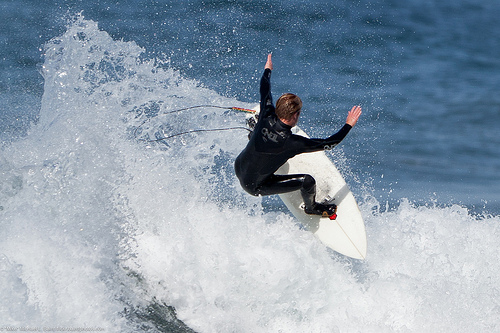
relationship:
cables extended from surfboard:
[149, 101, 257, 118] [241, 100, 368, 262]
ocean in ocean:
[2, 5, 498, 327] [2, 5, 498, 327]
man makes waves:
[231, 48, 361, 219] [90, 183, 305, 330]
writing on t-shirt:
[259, 126, 281, 146] [232, 114, 356, 187]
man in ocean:
[231, 48, 361, 219] [2, 5, 498, 327]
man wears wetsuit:
[231, 48, 361, 219] [239, 122, 317, 206]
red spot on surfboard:
[328, 213, 341, 220] [241, 100, 368, 262]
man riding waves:
[231, 48, 361, 219] [0, 0, 498, 332]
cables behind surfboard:
[149, 101, 256, 143] [241, 97, 376, 268]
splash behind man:
[11, 13, 500, 333] [231, 48, 361, 219]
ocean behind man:
[2, 5, 498, 327] [231, 48, 361, 219]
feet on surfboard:
[302, 196, 342, 221] [225, 91, 387, 271]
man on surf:
[231, 48, 361, 219] [264, 137, 372, 267]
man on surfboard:
[231, 48, 361, 219] [233, 97, 389, 264]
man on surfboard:
[231, 48, 361, 219] [241, 100, 368, 262]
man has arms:
[231, 48, 361, 219] [246, 45, 368, 146]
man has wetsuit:
[231, 48, 361, 219] [234, 68, 354, 220]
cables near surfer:
[153, 100, 263, 140] [241, 58, 371, 223]